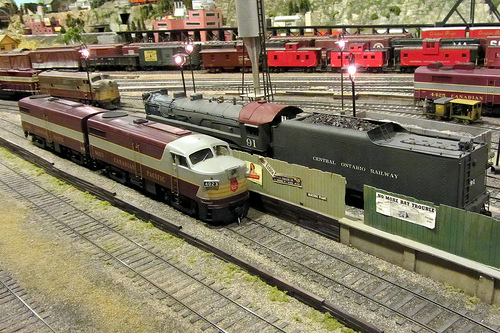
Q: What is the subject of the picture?
A: Trains.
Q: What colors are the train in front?
A: Red and gray.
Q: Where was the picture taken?
A: Train station.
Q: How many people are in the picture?
A: None.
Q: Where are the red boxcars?
A: At the back.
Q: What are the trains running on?
A: Tracks.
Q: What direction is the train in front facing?
A: Right.